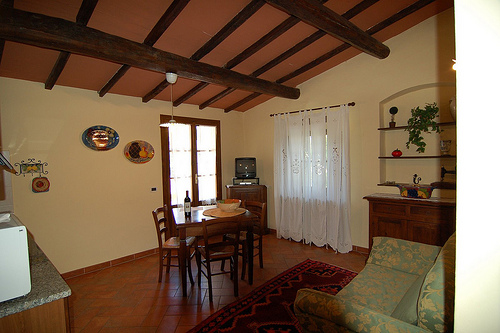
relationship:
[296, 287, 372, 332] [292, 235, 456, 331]
arm on chair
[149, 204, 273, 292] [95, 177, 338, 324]
table in room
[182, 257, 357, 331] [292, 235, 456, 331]
rug in front of chair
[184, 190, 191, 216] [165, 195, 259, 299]
bottle on table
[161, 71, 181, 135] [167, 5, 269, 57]
light hanging from ceiling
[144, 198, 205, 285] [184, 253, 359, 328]
chair on rug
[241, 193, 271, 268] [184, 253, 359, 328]
chair on rug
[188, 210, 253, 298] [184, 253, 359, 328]
chair on rug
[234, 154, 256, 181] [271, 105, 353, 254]
small television next to curtain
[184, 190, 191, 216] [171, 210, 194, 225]
bottle on table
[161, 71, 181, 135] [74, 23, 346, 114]
light hanging from beam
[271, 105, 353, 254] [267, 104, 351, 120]
curtain on rod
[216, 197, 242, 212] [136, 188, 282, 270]
bowl on wooden table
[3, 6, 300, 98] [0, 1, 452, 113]
beam on ceiling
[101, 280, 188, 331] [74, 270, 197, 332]
tiles on floor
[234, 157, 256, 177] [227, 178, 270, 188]
small television on stand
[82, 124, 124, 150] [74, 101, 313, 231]
plate on wall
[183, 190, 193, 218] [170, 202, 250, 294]
bottle on top of table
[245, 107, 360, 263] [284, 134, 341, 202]
curtain on window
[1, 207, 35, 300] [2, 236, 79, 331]
microwave on counter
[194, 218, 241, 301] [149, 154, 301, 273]
chair in front of table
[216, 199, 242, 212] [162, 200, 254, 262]
bowl on table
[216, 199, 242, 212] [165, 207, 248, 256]
bowl on table